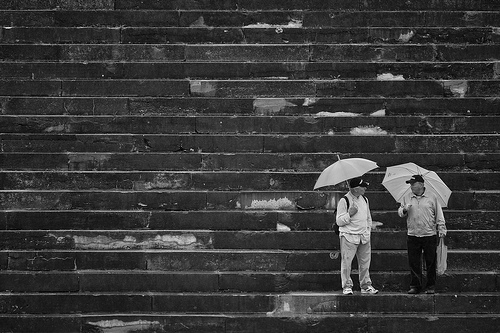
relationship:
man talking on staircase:
[397, 175, 448, 295] [0, 4, 497, 327]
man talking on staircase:
[335, 179, 379, 295] [0, 4, 497, 327]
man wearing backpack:
[335, 179, 379, 295] [327, 187, 352, 237]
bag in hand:
[435, 237, 450, 275] [435, 230, 448, 238]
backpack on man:
[326, 192, 354, 244] [330, 172, 380, 293]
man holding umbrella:
[397, 175, 448, 295] [383, 166, 452, 213]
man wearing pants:
[397, 175, 448, 295] [400, 235, 442, 294]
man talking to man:
[335, 179, 379, 295] [393, 167, 468, 294]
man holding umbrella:
[335, 179, 379, 295] [381, 157, 451, 211]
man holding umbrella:
[396, 174, 447, 281] [313, 157, 380, 195]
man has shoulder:
[325, 177, 384, 301] [332, 189, 361, 218]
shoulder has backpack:
[332, 189, 361, 218] [327, 187, 357, 239]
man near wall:
[397, 175, 448, 295] [3, 2, 483, 331]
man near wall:
[335, 179, 379, 295] [3, 2, 483, 331]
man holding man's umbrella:
[397, 175, 448, 295] [380, 162, 452, 208]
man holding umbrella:
[335, 179, 379, 295] [313, 150, 379, 191]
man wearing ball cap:
[335, 179, 379, 295] [406, 173, 428, 183]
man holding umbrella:
[335, 179, 379, 295] [310, 150, 384, 185]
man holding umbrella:
[397, 175, 448, 295] [387, 151, 450, 197]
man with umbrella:
[335, 179, 379, 295] [315, 148, 384, 189]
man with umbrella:
[397, 175, 448, 295] [382, 153, 458, 202]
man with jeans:
[335, 179, 379, 295] [332, 230, 384, 299]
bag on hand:
[436, 237, 448, 276] [436, 226, 451, 238]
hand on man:
[436, 226, 451, 238] [386, 151, 448, 279]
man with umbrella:
[335, 179, 379, 295] [311, 152, 378, 189]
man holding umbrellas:
[335, 179, 379, 295] [314, 152, 452, 207]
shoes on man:
[338, 284, 380, 297] [335, 179, 379, 295]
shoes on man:
[341, 287, 379, 296] [335, 179, 379, 295]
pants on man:
[406, 236, 439, 290] [396, 171, 451, 305]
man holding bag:
[397, 175, 448, 295] [433, 236, 450, 276]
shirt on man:
[327, 187, 387, 245] [335, 179, 379, 295]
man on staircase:
[397, 175, 448, 295] [0, 4, 497, 327]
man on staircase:
[335, 179, 379, 295] [0, 4, 497, 327]